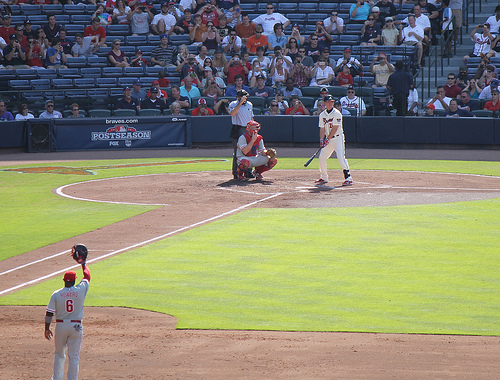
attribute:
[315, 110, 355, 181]
uniform — white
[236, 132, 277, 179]
padding — red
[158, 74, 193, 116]
man — sitting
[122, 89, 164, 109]
shirts — blue 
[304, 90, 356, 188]
player — Baseball player